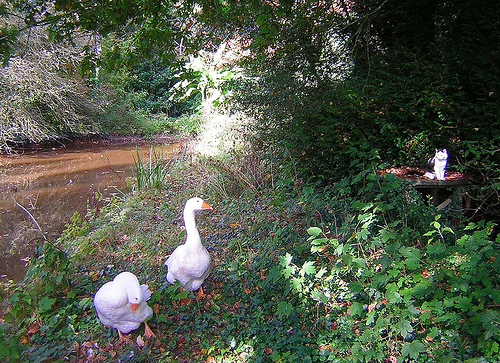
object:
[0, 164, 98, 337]
pond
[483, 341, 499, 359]
foliage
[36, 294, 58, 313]
leaf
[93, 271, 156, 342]
ducks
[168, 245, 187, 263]
feathers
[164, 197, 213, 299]
bird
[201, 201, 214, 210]
beak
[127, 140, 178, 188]
grass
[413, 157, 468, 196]
path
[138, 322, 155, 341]
foot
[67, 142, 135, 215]
water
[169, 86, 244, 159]
wall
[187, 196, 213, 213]
head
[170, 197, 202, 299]
goose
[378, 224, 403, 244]
leaf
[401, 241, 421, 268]
leaf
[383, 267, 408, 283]
leaf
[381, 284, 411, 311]
leaf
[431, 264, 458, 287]
leaf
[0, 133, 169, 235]
creek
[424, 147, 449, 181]
cat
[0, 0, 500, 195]
tree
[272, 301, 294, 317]
leaf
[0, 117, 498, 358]
garden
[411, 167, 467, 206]
bird bath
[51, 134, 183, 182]
river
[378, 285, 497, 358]
grass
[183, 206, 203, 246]
neck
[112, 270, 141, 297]
neck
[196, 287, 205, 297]
foot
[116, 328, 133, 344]
foot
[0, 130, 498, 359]
ground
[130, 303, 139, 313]
beak